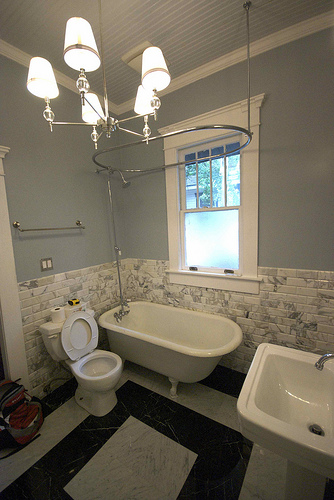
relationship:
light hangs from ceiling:
[27, 51, 59, 105] [3, 0, 331, 112]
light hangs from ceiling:
[67, 23, 99, 73] [3, 0, 331, 112]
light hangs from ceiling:
[83, 90, 102, 123] [3, 0, 331, 112]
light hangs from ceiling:
[135, 90, 154, 117] [3, 0, 331, 112]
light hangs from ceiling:
[140, 48, 168, 90] [3, 0, 331, 112]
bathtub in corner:
[99, 297, 241, 396] [110, 103, 128, 303]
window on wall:
[161, 95, 261, 293] [114, 30, 331, 370]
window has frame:
[161, 95, 261, 293] [157, 93, 266, 296]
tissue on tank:
[50, 306, 62, 325] [40, 317, 95, 362]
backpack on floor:
[3, 386, 45, 448] [1, 363, 326, 499]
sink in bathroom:
[236, 343, 333, 499] [3, 4, 329, 498]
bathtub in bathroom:
[99, 297, 241, 396] [3, 4, 329, 498]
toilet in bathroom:
[41, 310, 121, 416] [3, 4, 329, 498]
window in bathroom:
[161, 95, 261, 293] [3, 4, 329, 498]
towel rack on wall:
[14, 219, 87, 234] [1, 51, 117, 384]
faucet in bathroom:
[314, 347, 332, 370] [3, 4, 329, 498]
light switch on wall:
[42, 258, 54, 272] [1, 51, 117, 384]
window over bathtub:
[161, 95, 261, 293] [99, 297, 241, 396]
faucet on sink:
[314, 347, 332, 370] [236, 343, 333, 499]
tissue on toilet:
[50, 306, 62, 325] [41, 310, 121, 416]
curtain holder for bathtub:
[93, 123, 251, 182] [99, 297, 241, 396]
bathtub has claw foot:
[99, 297, 241, 396] [167, 377, 181, 396]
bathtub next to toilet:
[99, 297, 241, 396] [41, 310, 121, 416]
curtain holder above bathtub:
[93, 123, 251, 182] [99, 297, 241, 396]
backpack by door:
[3, 386, 45, 448] [0, 146, 34, 395]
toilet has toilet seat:
[41, 310, 121, 416] [63, 312, 99, 359]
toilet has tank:
[41, 310, 121, 416] [40, 317, 95, 362]